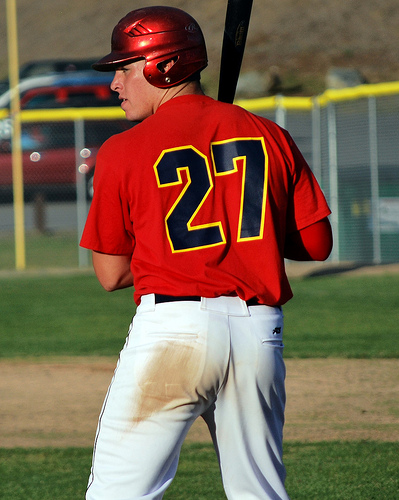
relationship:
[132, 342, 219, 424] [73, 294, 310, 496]
dirt on pants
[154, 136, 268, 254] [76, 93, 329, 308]
"27" on jersey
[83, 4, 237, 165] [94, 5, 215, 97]
man wears helmet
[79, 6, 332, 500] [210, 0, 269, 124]
man holding bat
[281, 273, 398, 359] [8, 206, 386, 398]
grass in field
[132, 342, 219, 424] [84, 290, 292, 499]
dirt on pants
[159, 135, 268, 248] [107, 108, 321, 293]
"27" on jersey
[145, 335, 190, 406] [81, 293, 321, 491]
dirt on pants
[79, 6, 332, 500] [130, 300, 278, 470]
man has pants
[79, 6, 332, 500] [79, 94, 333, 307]
man wearing jersey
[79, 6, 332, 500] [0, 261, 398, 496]
man on field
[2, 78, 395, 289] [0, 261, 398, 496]
fence around field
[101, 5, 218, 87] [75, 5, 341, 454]
helmet on player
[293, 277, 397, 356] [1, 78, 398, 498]
grass on baseball field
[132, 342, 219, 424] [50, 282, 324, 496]
dirt on pants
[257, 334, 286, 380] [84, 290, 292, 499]
pocket on pants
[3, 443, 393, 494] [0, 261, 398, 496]
grass on field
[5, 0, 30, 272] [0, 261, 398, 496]
pole on field